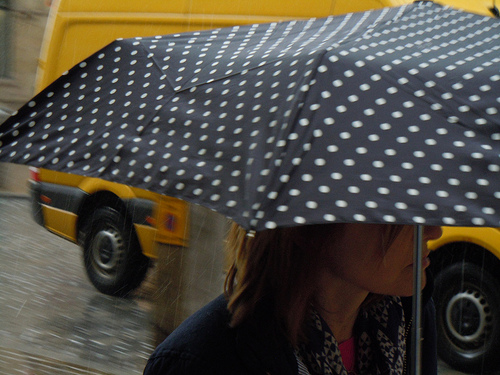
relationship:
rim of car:
[85, 221, 126, 281] [30, 0, 500, 375]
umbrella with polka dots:
[10, 2, 499, 237] [0, 0, 499, 233]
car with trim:
[30, 0, 500, 375] [33, 175, 158, 226]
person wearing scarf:
[141, 222, 441, 374] [296, 292, 403, 374]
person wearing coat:
[141, 222, 441, 374] [141, 274, 440, 375]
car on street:
[30, 0, 500, 375] [2, 3, 497, 373]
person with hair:
[141, 222, 441, 374] [221, 222, 403, 347]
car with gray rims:
[30, 0, 500, 375] [81, 218, 496, 352]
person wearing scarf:
[141, 222, 441, 374] [267, 273, 417, 373]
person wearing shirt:
[141, 222, 441, 374] [334, 331, 356, 369]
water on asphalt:
[2, 195, 141, 372] [1, 187, 165, 373]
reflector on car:
[20, 162, 42, 191] [30, 0, 500, 375]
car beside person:
[166, 5, 233, 26] [141, 222, 441, 374]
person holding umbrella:
[141, 222, 441, 374] [10, 2, 499, 237]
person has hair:
[141, 222, 441, 374] [221, 222, 403, 347]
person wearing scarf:
[141, 222, 441, 374] [293, 302, 416, 373]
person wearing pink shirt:
[141, 222, 441, 374] [334, 340, 358, 373]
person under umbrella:
[141, 222, 441, 374] [10, 2, 499, 237]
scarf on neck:
[289, 277, 410, 373] [324, 272, 373, 347]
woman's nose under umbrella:
[424, 227, 442, 241] [296, 87, 459, 157]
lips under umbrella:
[406, 251, 436, 271] [296, 87, 459, 157]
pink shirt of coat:
[334, 340, 363, 375] [141, 280, 437, 372]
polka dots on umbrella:
[0, 0, 499, 233] [2, 1, 496, 373]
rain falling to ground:
[0, 243, 83, 357] [88, 316, 136, 372]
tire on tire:
[79, 200, 175, 309] [75, 202, 155, 299]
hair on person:
[214, 217, 412, 348] [141, 222, 441, 374]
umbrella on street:
[10, 2, 499, 237] [2, 194, 497, 374]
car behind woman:
[30, 0, 500, 375] [248, 207, 420, 334]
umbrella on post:
[10, 2, 499, 237] [408, 226, 425, 369]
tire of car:
[75, 202, 155, 299] [30, 0, 500, 375]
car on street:
[30, 0, 500, 375] [1, 196, 159, 373]